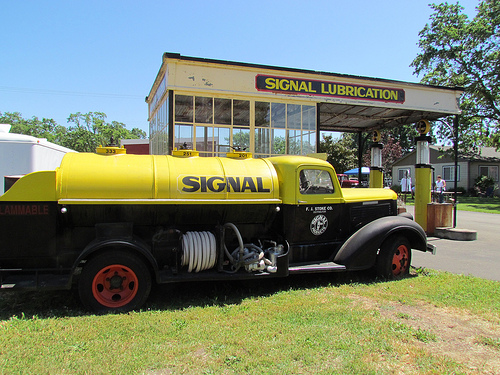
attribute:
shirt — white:
[435, 179, 444, 189]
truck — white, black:
[3, 138, 442, 315]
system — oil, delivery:
[168, 208, 290, 280]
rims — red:
[67, 230, 439, 333]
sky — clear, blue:
[26, 1, 152, 124]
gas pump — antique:
[408, 117, 438, 241]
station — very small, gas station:
[132, 44, 499, 231]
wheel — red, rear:
[83, 252, 149, 314]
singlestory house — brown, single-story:
[389, 145, 499, 196]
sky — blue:
[2, 0, 481, 138]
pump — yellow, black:
[409, 115, 435, 242]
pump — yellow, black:
[365, 123, 387, 187]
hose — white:
[186, 230, 211, 264]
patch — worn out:
[331, 283, 498, 372]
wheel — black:
[77, 244, 147, 313]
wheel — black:
[376, 232, 411, 280]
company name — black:
[180, 175, 270, 193]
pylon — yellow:
[367, 166, 384, 188]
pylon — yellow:
[413, 164, 431, 234]